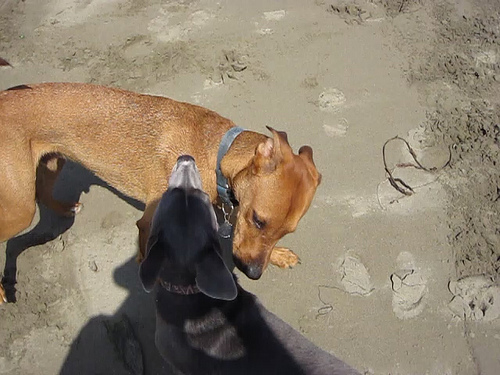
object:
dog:
[0, 82, 322, 304]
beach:
[1, 0, 499, 374]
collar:
[216, 126, 249, 206]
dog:
[137, 153, 362, 373]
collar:
[158, 279, 200, 292]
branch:
[383, 144, 408, 196]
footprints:
[315, 88, 352, 138]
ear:
[252, 124, 297, 175]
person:
[53, 246, 303, 374]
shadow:
[62, 193, 307, 374]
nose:
[242, 261, 264, 280]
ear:
[193, 248, 239, 300]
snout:
[167, 154, 202, 190]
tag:
[217, 221, 235, 238]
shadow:
[3, 151, 145, 303]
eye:
[250, 209, 267, 230]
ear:
[299, 145, 323, 185]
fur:
[77, 100, 130, 148]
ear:
[138, 236, 167, 292]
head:
[227, 125, 322, 280]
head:
[138, 154, 240, 301]